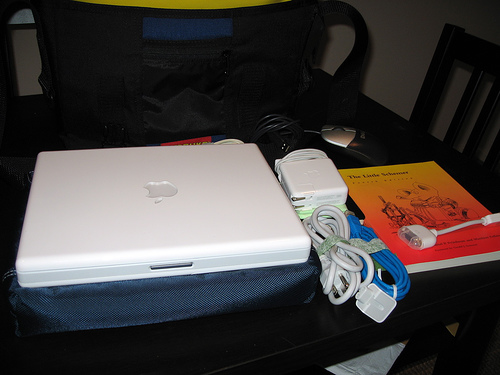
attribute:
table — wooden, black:
[2, 59, 498, 373]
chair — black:
[393, 16, 499, 164]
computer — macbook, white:
[15, 139, 312, 292]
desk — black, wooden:
[3, 45, 496, 363]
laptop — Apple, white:
[11, 138, 313, 295]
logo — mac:
[144, 180, 179, 200]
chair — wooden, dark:
[402, 20, 498, 155]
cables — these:
[304, 205, 414, 325]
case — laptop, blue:
[5, 246, 323, 331]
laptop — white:
[20, 143, 312, 288]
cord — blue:
[348, 215, 420, 297]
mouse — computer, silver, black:
[318, 119, 388, 168]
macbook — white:
[11, 138, 314, 295]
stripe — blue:
[141, 17, 229, 40]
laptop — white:
[10, 131, 332, 338]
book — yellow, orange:
[334, 159, 499, 272]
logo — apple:
[140, 172, 185, 207]